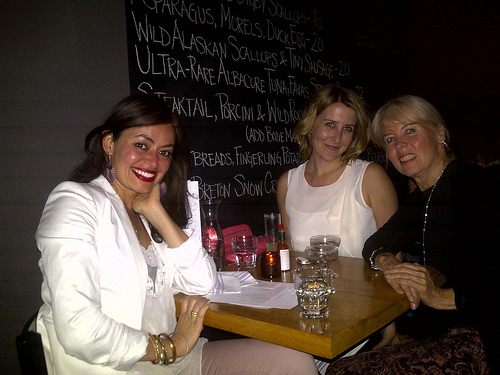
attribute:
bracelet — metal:
[167, 328, 191, 365]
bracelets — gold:
[151, 328, 178, 368]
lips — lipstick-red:
[122, 162, 177, 195]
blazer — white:
[10, 145, 252, 373]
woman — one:
[29, 89, 250, 374]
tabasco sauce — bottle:
[276, 224, 288, 271]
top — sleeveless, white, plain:
[288, 160, 459, 300]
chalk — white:
[130, 0, 385, 200]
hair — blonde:
[371, 95, 446, 149]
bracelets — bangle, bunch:
[140, 298, 204, 373]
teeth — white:
[130, 164, 159, 182]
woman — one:
[35, 75, 497, 366]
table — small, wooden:
[205, 235, 420, 355]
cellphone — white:
[296, 255, 320, 267]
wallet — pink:
[205, 222, 277, 264]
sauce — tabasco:
[273, 222, 295, 272]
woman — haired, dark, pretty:
[28, 92, 315, 374]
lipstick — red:
[133, 164, 155, 182]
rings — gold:
[187, 307, 198, 322]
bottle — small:
[280, 232, 291, 265]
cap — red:
[276, 219, 286, 233]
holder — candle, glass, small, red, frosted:
[255, 251, 272, 267]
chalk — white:
[200, 68, 238, 82]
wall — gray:
[29, 31, 79, 101]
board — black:
[209, 92, 262, 184]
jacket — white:
[76, 215, 146, 355]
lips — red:
[131, 162, 159, 186]